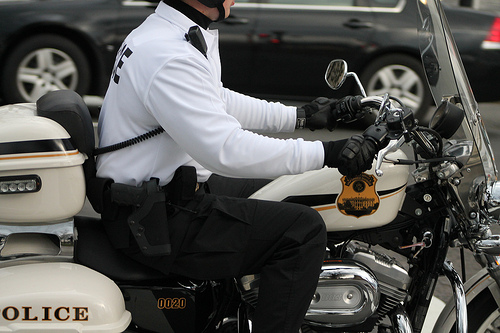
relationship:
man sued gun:
[72, 0, 395, 333] [108, 175, 170, 256]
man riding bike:
[72, 0, 395, 333] [300, 0, 493, 327]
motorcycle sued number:
[0, 0, 500, 333] [153, 287, 185, 313]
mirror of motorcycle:
[318, 60, 349, 90] [8, 22, 498, 325]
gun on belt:
[105, 177, 173, 268] [86, 164, 223, 220]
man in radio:
[72, 0, 395, 333] [187, 25, 208, 57]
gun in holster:
[108, 178, 161, 208] [123, 175, 173, 260]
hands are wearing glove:
[298, 91, 390, 187] [323, 132, 378, 177]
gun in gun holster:
[105, 177, 173, 268] [106, 175, 172, 267]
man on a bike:
[72, 0, 395, 333] [240, 47, 478, 309]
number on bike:
[150, 290, 190, 316] [9, 93, 495, 323]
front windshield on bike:
[416, 0, 498, 193] [3, 33, 492, 308]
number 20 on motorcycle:
[156, 294, 187, 309] [8, 65, 483, 316]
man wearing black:
[72, 0, 395, 333] [277, 257, 310, 277]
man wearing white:
[72, 0, 395, 333] [241, 100, 271, 121]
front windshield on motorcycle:
[416, 0, 498, 193] [8, 22, 498, 325]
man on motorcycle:
[72, 0, 395, 333] [8, 22, 498, 325]